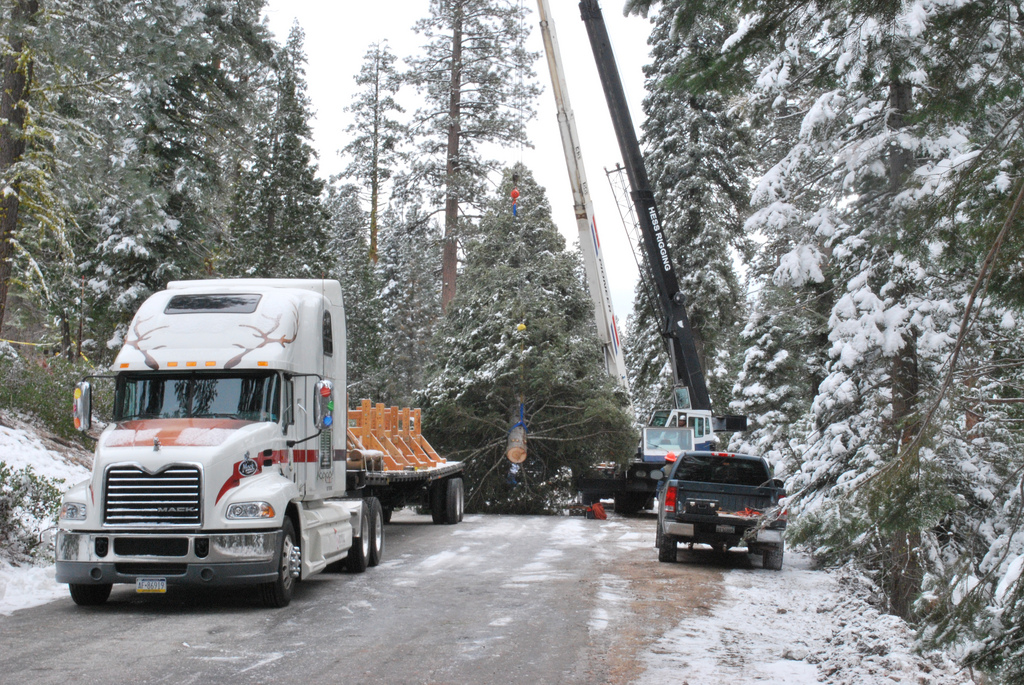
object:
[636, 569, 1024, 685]
snow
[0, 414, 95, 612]
snow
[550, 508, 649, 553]
snow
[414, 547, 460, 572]
snow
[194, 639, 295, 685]
snow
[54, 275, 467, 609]
truck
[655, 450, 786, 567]
truck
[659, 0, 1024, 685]
snow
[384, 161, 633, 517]
snow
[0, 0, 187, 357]
snow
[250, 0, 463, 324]
snow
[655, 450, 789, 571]
pick up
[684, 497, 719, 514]
toolbox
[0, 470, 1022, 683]
ground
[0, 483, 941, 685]
road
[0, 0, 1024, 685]
trees